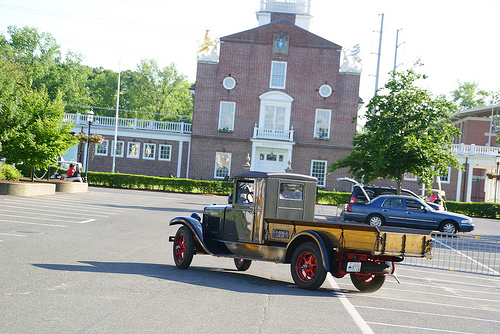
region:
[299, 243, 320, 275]
red rims on the truck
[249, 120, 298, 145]
balcony on the building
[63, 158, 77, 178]
man in a golf cart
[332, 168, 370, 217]
trunk open on the car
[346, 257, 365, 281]
license plate on the truck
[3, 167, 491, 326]
old-fashioned truck parked in lot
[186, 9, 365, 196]
symmetrical building with round and rectangular windows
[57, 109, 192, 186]
building with square windows and roof railing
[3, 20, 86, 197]
green tree in back of low tan partitions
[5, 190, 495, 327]
white lines marking parking spaces in lot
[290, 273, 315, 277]
the view of a white wall and chairs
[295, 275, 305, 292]
the view of a white wall and chairs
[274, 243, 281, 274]
the view of a white wall and chairs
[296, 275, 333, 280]
the view of a white wall and chairs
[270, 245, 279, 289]
the view of a white wall and chairs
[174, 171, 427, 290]
old timey car parked in the lot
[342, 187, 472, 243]
car parking the lot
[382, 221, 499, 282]
metal railing in the parking lot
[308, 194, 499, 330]
white lines painted on the parking lot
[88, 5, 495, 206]
red brick building in the background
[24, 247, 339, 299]
shadow of the truck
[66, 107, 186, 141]
white railing on the brick building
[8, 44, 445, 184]
trees in the parking lot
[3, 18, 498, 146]
trees behind the brick building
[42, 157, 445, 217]
two golf carts driving through the parking lot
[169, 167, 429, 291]
An antique truck in a parking lot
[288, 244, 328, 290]
A rear tire on a truck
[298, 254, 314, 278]
A red rim on a truck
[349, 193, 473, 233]
A blue car in a parking lot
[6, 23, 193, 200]
A set of trees to the left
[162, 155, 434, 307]
A classic truck in the parking lot